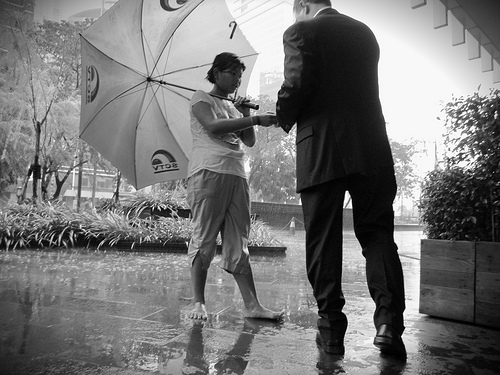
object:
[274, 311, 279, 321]
toe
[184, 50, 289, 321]
human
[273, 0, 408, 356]
human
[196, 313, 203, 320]
toe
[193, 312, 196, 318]
toe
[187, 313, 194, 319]
toe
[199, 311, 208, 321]
toe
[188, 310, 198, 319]
toe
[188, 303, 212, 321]
foot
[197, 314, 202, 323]
toe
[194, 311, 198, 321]
toe